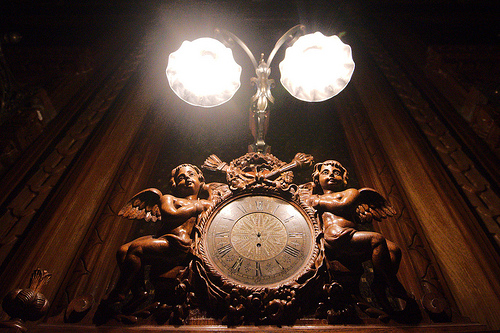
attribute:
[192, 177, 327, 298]
clock — old, antique, handless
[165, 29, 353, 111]
sources — light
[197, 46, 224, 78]
bulb — shining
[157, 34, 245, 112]
shade — glass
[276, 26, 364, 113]
edge — scalloped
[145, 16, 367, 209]
fixture — lighting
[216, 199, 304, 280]
numerals — roman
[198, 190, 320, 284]
face — clock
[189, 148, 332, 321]
wood — carved, intricate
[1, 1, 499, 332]
wall — paneled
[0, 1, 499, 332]
panel — wood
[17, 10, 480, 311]
wood — dark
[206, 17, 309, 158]
metal — decorated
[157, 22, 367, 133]
light — shinning, bright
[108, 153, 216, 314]
statue — angel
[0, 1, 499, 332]
scene — night time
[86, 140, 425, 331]
decorations — wooden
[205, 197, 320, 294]
numbers — roman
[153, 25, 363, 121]
lamps — bright, turned on